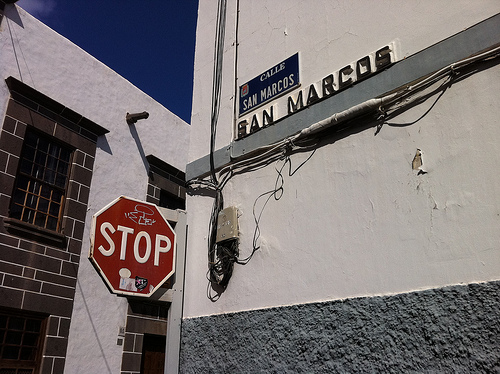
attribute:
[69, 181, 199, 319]
sign — red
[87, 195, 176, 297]
stop sign — red 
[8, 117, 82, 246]
railing. — wood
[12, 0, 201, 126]
sky — blue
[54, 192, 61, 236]
bars — metal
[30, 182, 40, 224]
bars — metal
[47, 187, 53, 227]
bars — metal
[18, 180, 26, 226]
bars — metal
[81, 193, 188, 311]
sign — white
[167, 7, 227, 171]
border — blue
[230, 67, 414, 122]
letters — black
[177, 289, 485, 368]
stucco — grey